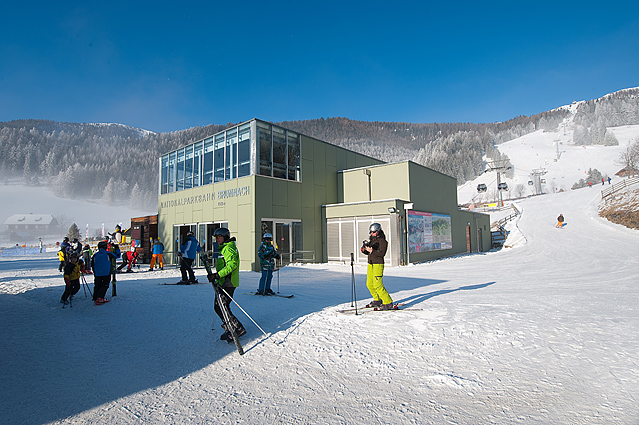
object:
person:
[360, 223, 393, 310]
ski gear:
[335, 299, 423, 315]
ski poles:
[350, 252, 359, 315]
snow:
[308, 293, 639, 401]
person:
[207, 228, 248, 343]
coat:
[215, 237, 239, 287]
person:
[257, 233, 281, 296]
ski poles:
[262, 252, 280, 296]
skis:
[243, 291, 295, 299]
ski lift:
[484, 159, 512, 207]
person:
[56, 247, 68, 272]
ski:
[62, 286, 73, 309]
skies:
[0, 0, 639, 133]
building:
[158, 117, 491, 272]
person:
[148, 239, 165, 271]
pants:
[149, 254, 163, 268]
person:
[556, 214, 564, 229]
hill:
[502, 174, 639, 359]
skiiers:
[90, 241, 121, 305]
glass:
[225, 143, 236, 180]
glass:
[214, 132, 223, 183]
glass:
[260, 129, 272, 177]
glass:
[273, 131, 286, 179]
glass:
[288, 136, 300, 181]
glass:
[176, 160, 183, 190]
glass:
[239, 139, 250, 177]